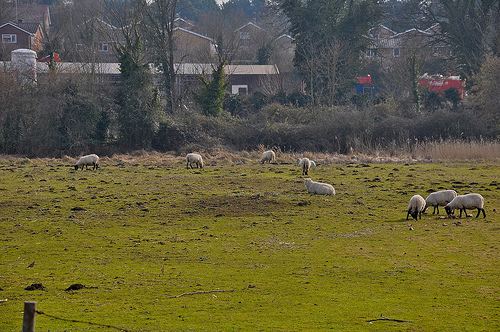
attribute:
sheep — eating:
[407, 193, 425, 218]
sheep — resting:
[300, 174, 340, 199]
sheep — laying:
[297, 177, 340, 209]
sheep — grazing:
[408, 195, 425, 218]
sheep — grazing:
[424, 194, 451, 207]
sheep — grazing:
[443, 193, 487, 215]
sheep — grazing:
[306, 172, 333, 189]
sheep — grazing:
[76, 157, 101, 164]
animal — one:
[173, 151, 215, 177]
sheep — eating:
[72, 150, 100, 172]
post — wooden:
[19, 294, 36, 329]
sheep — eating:
[445, 192, 487, 219]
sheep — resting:
[302, 174, 335, 198]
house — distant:
[1, 19, 49, 64]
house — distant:
[55, 20, 142, 68]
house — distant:
[150, 24, 217, 72]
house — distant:
[222, 20, 276, 61]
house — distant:
[373, 22, 457, 64]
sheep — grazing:
[259, 147, 276, 163]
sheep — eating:
[179, 139, 209, 171]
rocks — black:
[22, 281, 93, 293]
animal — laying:
[301, 174, 337, 196]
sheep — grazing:
[442, 188, 485, 222]